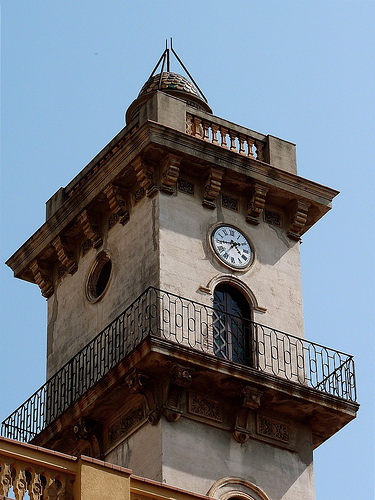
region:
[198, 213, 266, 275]
clock on the building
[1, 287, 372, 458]
metal fence around the top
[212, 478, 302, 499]
round under the railing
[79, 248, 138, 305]
window on the side of building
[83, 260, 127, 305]
window is round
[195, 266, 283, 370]
door under the clock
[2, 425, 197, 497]
cement railing on the next level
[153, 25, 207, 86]
pipes come to a point on the top of building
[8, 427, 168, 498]
railing has a reddish orange color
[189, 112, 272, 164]
pillars on the wall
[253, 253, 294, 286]
part of a shade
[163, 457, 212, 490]
edge of a shade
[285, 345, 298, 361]
part of a balcony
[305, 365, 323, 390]
part of a metal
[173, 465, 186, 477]
edge of a shade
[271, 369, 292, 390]
edge of a line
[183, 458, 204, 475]
part of a shade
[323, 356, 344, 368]
part of a balcony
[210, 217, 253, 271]
that is a clock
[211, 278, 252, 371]
that is a window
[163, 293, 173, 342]
that is a metal bar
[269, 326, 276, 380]
that is a metal bar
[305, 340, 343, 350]
that is a metal bar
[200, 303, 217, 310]
that is a metal bar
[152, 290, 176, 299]
that is a metal bar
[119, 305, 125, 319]
that is a metal bar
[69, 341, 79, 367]
that is a metal bar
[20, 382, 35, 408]
that is a metal bar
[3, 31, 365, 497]
a historic looking clocktower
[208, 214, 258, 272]
round clock with a white face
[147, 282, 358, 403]
balcony made of wrought iron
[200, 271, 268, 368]
arched doorway beneath clock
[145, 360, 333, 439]
detailed sculpture work on clock tower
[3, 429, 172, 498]
part of a fence to a balcony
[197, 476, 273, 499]
arched doorway under balcony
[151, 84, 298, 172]
railing to the roof balcony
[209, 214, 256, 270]
clock with roman numerals on face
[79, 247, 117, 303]
window in side wall of clock tower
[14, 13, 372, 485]
Photo taken during the day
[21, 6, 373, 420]
The sky is clear and blue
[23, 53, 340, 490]
Large concrete tower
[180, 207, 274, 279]
Clock on the tower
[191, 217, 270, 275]
Clock face is white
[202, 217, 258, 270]
Clock hands are black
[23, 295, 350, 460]
Balcony around the tower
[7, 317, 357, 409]
Balcony railings are metal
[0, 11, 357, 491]
Nobody in the photo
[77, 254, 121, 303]
Round window in the tower